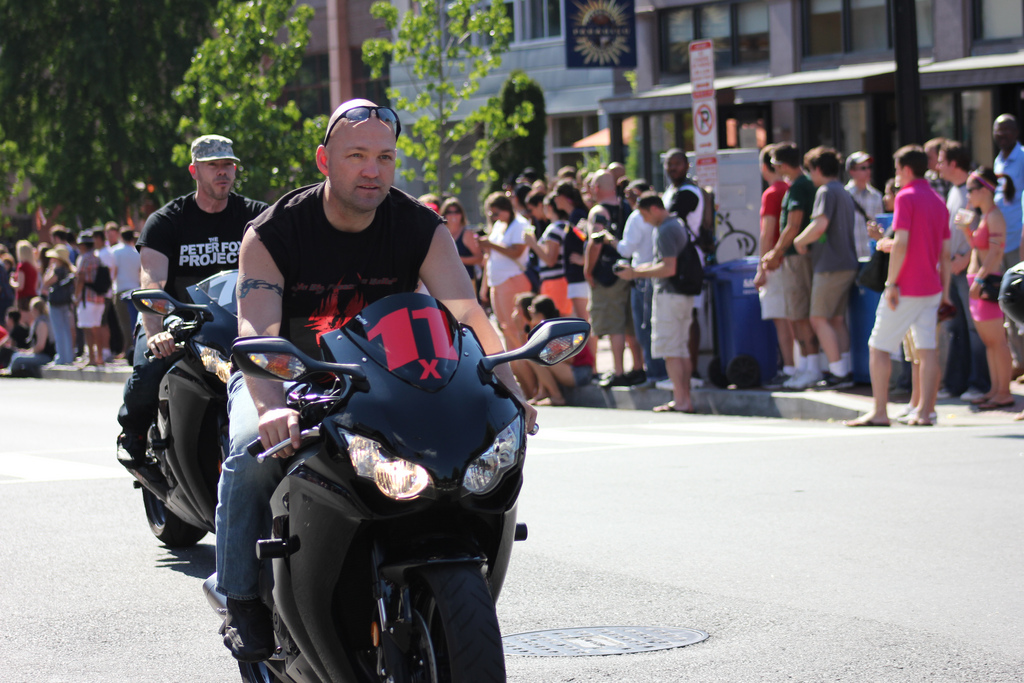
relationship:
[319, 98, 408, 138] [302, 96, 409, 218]
sunglasses on head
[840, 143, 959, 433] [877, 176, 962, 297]
man wears shirt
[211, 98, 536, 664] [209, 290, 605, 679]
man riding motorcycle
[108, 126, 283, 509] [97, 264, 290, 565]
man riding motorcycle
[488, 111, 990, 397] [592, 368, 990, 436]
people on sidewalk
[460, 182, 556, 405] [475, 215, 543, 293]
woman wears top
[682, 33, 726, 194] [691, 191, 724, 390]
signs on pole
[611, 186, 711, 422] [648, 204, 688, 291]
man wearing shirt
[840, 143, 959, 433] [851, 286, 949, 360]
man wearing shorts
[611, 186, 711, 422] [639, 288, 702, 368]
man wearing shorts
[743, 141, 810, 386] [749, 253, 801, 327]
man wearing shorts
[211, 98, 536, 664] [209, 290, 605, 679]
man on motorcycle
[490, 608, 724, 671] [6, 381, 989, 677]
manhole on ground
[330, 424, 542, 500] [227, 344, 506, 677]
headlights are on motorcycle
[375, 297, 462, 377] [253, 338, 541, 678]
number on motorcycle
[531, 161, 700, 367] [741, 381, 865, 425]
people are standing on sidewalk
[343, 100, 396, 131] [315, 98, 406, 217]
glasses are on top of head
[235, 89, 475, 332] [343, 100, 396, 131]
man has glasses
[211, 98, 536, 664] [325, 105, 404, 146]
man wearing sunglasses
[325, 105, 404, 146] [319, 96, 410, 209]
sunglasses are on head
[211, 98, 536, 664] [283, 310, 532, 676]
man riding a motorcycle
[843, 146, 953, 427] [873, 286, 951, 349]
man wearing shorts